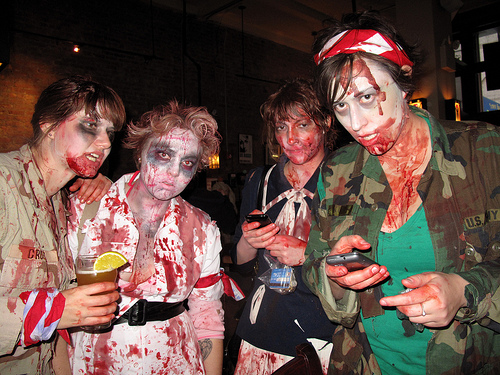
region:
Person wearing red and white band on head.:
[330, 25, 408, 62]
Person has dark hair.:
[321, 60, 346, 87]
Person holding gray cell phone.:
[324, 237, 377, 289]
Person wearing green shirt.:
[381, 238, 408, 253]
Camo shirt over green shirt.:
[443, 162, 475, 232]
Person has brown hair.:
[263, 88, 306, 111]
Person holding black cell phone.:
[236, 205, 280, 252]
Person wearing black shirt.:
[271, 299, 293, 319]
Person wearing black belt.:
[134, 295, 186, 331]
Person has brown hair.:
[31, 78, 103, 132]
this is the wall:
[13, 82, 31, 119]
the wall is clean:
[6, 92, 36, 127]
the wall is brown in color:
[11, 91, 36, 133]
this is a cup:
[81, 253, 136, 335]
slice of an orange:
[90, 251, 135, 282]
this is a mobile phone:
[318, 249, 398, 288]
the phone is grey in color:
[353, 255, 364, 268]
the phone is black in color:
[250, 217, 260, 221]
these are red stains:
[164, 259, 173, 296]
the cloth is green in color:
[400, 248, 425, 265]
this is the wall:
[6, 67, 26, 104]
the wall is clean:
[9, 74, 24, 114]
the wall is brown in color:
[12, 67, 28, 102]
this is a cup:
[80, 255, 124, 328]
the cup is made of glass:
[77, 263, 120, 330]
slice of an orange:
[90, 249, 133, 274]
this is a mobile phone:
[324, 247, 386, 280]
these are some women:
[14, 61, 497, 357]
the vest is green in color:
[393, 244, 430, 260]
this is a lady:
[129, 100, 223, 222]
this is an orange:
[92, 250, 124, 268]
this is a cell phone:
[321, 237, 379, 279]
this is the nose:
[352, 113, 367, 128]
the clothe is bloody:
[159, 220, 208, 305]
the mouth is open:
[85, 147, 102, 170]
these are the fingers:
[395, 270, 473, 325]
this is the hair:
[151, 107, 191, 133]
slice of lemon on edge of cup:
[93, 247, 128, 280]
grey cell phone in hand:
[321, 245, 383, 279]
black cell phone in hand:
[238, 207, 276, 239]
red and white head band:
[308, 20, 421, 74]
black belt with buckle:
[119, 288, 191, 330]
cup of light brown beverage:
[63, 248, 125, 334]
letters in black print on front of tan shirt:
[21, 239, 51, 265]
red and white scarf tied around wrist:
[9, 283, 81, 360]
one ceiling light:
[63, 37, 93, 57]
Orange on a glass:
[89, 247, 126, 277]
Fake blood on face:
[58, 146, 113, 187]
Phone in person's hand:
[325, 249, 380, 285]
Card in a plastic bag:
[258, 268, 297, 293]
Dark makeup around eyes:
[139, 137, 176, 172]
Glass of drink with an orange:
[55, 247, 132, 343]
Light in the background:
[195, 144, 223, 179]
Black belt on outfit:
[116, 288, 188, 334]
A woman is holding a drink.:
[70, 250, 126, 327]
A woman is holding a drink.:
[73, 245, 122, 327]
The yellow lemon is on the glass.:
[93, 245, 119, 273]